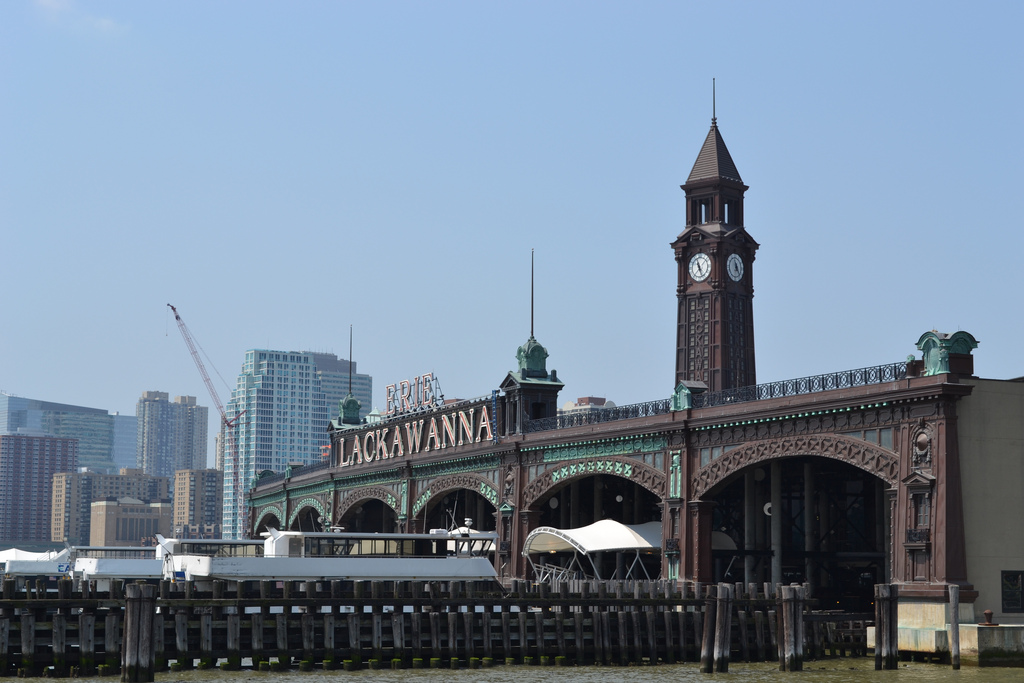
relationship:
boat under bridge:
[523, 514, 739, 576] [256, 321, 1016, 577]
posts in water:
[867, 582, 894, 669] [14, 654, 1021, 678]